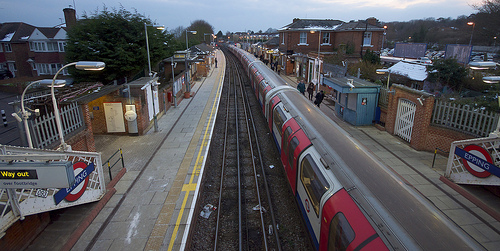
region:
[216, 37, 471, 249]
large red and gray train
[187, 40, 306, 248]
black train tracks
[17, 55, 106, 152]
gray large lampposts on left platform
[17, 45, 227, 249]
platform in the left side with yellow line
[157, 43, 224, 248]
yellow line in floor of pavement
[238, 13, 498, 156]
a bunch of houses on right side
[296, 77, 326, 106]
people on right side platform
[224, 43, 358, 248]
a bun ch of windows on red and gray train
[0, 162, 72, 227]
black yellow and white signboard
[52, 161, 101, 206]
red blue and white symbol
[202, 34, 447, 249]
a long train on a track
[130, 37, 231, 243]
a train station plate form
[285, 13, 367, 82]
a red brick building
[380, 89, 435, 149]
a white gate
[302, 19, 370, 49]
a building with a shingled roof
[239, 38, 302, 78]
several people standing in front of a building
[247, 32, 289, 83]
several people standing near a train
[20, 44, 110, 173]
two security lights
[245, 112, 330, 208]
a red door on a train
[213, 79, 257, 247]
a set of train tracks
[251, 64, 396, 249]
the train is long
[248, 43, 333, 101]
people are on the sidewalk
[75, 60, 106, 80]
the light is on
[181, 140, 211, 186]
the yellow line is on the pavement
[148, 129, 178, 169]
the pavement is grey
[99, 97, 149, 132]
the wall is made of bricks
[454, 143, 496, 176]
the sign says epping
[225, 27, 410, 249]
the train is public transport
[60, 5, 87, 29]
the chimney is made of bricks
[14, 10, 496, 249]
the photo was taken during the day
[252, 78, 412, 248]
the train at the platform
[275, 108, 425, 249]
the train is red and white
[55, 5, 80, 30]
the chimney of the house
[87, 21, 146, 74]
the tree with green leaves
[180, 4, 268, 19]
the clouds in the ksy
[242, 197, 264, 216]
garbage on the tracks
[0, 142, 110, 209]
the ramp to the platform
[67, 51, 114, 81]
the light above the platform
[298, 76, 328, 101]
people on the platform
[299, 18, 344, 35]
snow on the roof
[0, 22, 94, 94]
Brick buildings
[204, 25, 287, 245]
Train tracks next to red and white train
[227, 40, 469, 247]
Red and white train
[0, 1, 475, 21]
Sky completely covered in clouds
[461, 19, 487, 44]
One of many street lights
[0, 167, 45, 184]
Sign saying way out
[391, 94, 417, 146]
White gate in the midst of fence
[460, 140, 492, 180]
Red white and blue sign saying epping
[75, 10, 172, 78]
Green tree behind buildings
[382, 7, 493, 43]
Woods off in the distance